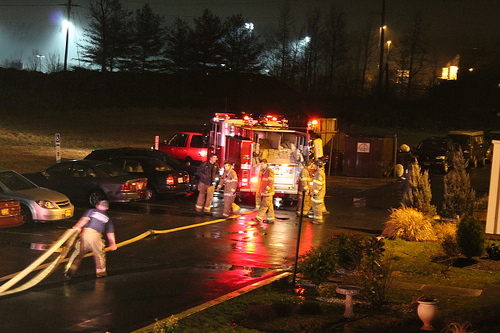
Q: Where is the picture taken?
A: Parking lot.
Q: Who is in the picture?
A: Firemen.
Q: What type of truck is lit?
A: Fire Truck.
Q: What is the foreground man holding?
A: Hoses.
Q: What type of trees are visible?
A: Evergreen.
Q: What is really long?
A: The hose.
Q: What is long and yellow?
A: The hose.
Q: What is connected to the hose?
A: Fire truck.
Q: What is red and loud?
A: Fire truck.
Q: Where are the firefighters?
A: Around the truck.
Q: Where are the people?
A: Outside of the truck.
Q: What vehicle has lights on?
A: Fire truck.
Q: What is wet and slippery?
A: The road.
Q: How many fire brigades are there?
A: 1.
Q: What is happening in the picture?
A: Firefighters have just finished putting off a fire.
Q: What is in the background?
A: Trees.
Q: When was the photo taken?
A: At night.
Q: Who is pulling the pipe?
A: A man.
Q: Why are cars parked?
A: It's a parking lot.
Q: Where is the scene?
A: At an emergency.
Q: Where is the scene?
A: A parking lot.